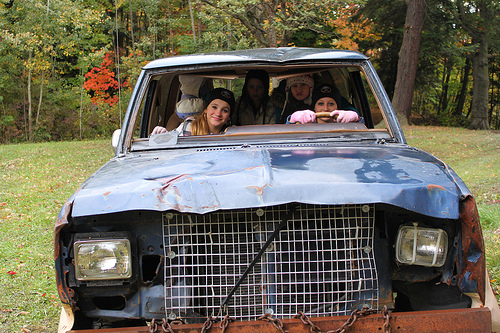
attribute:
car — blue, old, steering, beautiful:
[67, 52, 496, 321]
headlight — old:
[396, 221, 464, 283]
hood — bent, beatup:
[103, 147, 445, 223]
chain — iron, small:
[159, 304, 392, 332]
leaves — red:
[88, 67, 114, 97]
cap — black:
[315, 82, 333, 95]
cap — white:
[287, 74, 320, 87]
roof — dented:
[168, 49, 358, 65]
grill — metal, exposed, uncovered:
[171, 202, 369, 300]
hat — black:
[201, 90, 236, 103]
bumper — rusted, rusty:
[150, 309, 497, 332]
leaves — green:
[40, 20, 91, 48]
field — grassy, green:
[13, 139, 130, 318]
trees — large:
[19, 15, 499, 103]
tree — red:
[85, 48, 129, 141]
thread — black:
[242, 226, 279, 288]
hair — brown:
[192, 109, 207, 135]